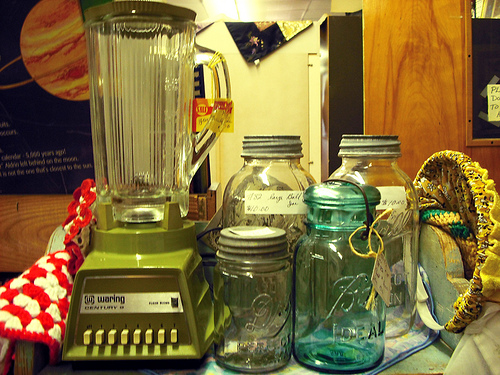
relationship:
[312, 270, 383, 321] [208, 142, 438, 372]
writing on jars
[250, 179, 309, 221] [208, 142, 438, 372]
stickers on jars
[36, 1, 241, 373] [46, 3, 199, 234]
blender has pitcher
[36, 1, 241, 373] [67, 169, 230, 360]
blender has base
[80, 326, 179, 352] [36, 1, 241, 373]
buttons on blender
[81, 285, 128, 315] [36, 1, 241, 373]
logo on blender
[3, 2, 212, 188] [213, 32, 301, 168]
poster on wall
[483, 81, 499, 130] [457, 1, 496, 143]
note on window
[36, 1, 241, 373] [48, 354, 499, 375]
blender on table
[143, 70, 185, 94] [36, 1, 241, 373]
words on blender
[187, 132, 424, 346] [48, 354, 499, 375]
glass on table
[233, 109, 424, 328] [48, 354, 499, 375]
glasses on table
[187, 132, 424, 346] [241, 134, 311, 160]
glass has top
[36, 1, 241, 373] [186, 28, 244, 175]
blender has handle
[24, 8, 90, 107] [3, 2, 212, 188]
planet on poster